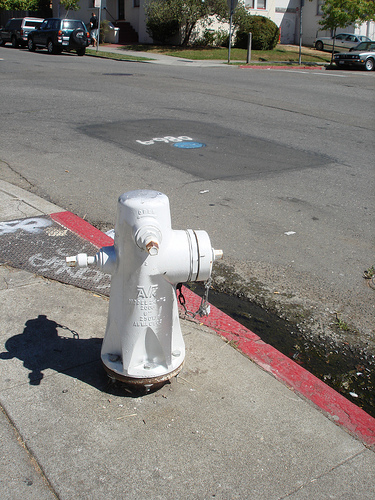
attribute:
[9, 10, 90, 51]
jeep — green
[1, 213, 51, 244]
spray paint —  white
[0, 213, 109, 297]
metal grate —  metal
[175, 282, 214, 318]
chain — hydrant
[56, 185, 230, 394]
hydrant — fire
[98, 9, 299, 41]
house — in distance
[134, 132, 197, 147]
marking — white, on road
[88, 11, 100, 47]
person — walking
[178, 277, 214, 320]
chain — metal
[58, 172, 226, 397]
hydrant — metal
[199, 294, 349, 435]
sidewalk — red area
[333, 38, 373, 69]
car — parked 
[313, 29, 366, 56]
car — parked 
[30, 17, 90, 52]
car — parked 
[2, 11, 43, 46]
car — parked 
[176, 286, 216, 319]
chain — silver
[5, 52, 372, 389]
road — side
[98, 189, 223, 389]
fire hydrant — white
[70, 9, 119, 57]
man — blue, hole cover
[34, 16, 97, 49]
green car — parked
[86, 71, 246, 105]
road — side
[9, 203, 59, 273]
graffiti — white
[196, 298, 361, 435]
line — red, painted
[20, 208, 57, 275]
graffiti — white